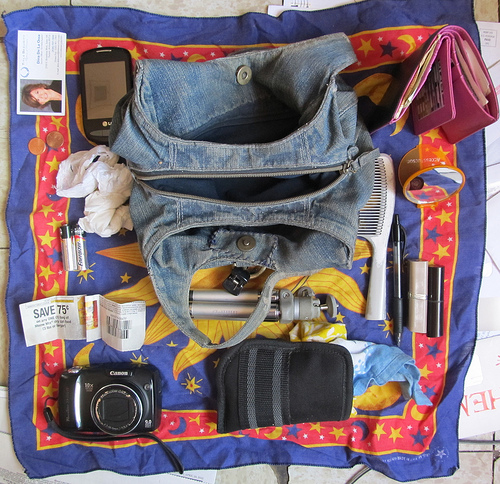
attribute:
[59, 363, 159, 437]
camera — black, cannon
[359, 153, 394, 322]
comb — white, plastic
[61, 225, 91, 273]
batteries — aa, joined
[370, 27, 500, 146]
wallet — pink, open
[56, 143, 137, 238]
tissue — crumbled, wadded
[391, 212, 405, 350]
pen — black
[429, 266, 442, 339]
lipsitck — tube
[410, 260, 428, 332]
lipsitck — tube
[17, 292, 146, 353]
coupon — white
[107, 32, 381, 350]
purse — denim, blue, jean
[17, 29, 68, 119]
card — rectangular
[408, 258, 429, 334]
lipstick — tube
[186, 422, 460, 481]
bandana — full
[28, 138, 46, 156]
penny — cooper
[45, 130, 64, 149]
penny — cooper